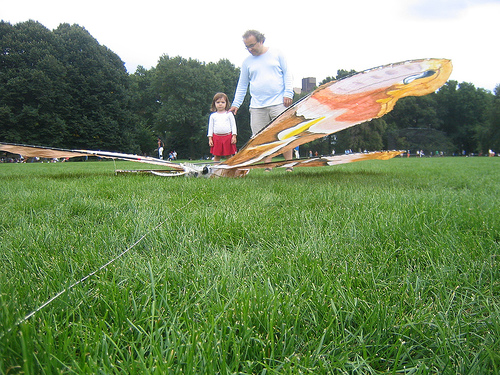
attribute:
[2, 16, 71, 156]
tree — tall, green, dark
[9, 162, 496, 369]
grass — area, green 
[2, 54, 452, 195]
kite — looks like a butterfly, colorful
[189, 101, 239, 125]
shirt — white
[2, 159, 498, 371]
field — green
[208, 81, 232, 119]
hair — brown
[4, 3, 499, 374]
photo — taken outdoors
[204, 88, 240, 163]
girl — young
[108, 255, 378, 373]
grass — short, green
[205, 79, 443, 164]
kite — orange, yellow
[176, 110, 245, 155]
shirt — white, long sleeved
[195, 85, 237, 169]
girl — young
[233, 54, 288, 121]
shirt — blue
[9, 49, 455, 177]
kite — insect shaped, large 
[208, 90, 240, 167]
child — small